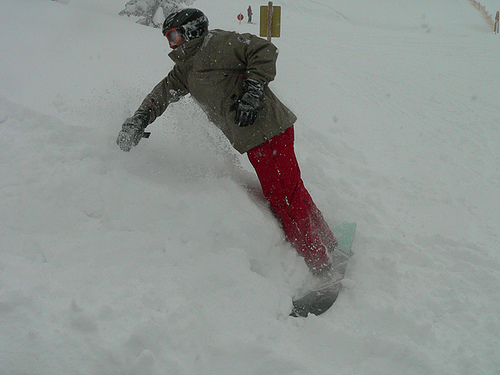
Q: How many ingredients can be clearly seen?
A: 6.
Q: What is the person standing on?
A: A snowboard.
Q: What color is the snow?
A: White.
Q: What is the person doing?
A: Snowboarding.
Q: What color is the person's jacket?
A: Gray.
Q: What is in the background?
A: A sign.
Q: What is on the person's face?
A: Goggles.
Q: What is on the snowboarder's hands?
A: Gloves.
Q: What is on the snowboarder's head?
A: A helmet.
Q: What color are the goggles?
A: Orange.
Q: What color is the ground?
A: White.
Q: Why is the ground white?
A: Snow.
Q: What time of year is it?
A: Winter.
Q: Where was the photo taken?
A: Ski slope.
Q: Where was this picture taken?
A: Snow slopes.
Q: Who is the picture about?
A: A snowboarder.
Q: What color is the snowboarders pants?
A: Red.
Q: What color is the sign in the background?
A: Yellow.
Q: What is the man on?
A: A snowboard.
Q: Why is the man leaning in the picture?
A: He Is falling.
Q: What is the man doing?
A: Snowboarding.